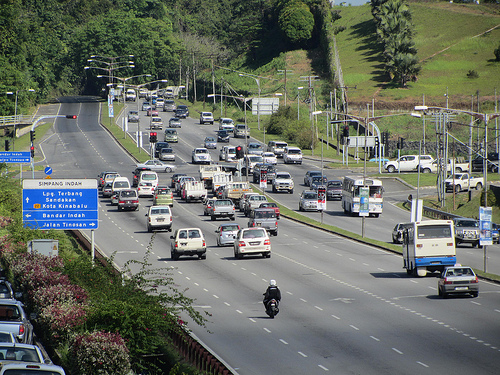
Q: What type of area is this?
A: Highway.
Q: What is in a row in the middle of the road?
A: Lights.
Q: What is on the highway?
A: Traffic.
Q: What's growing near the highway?
A: Trees.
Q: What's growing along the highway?
A: Bushes.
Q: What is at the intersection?
A: Vehicles.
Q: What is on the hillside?
A: Trees.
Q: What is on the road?
A: Cars.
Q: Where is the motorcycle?
A: On the road.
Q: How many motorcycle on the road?
A: One.